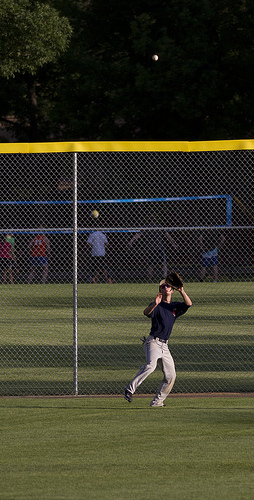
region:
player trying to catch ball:
[132, 35, 203, 353]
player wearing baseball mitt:
[139, 265, 189, 340]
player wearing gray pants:
[138, 275, 186, 414]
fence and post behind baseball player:
[28, 237, 221, 403]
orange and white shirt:
[27, 224, 63, 259]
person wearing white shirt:
[82, 221, 114, 287]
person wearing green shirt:
[7, 223, 22, 259]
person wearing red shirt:
[2, 232, 18, 289]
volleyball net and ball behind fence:
[20, 187, 225, 234]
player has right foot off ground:
[110, 273, 174, 422]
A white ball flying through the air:
[150, 48, 161, 66]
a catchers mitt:
[164, 267, 189, 298]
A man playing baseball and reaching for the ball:
[116, 267, 202, 411]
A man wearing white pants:
[121, 331, 180, 403]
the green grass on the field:
[50, 416, 162, 476]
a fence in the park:
[183, 169, 230, 190]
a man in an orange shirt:
[26, 228, 53, 260]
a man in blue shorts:
[195, 244, 229, 278]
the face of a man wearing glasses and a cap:
[157, 276, 175, 301]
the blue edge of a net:
[19, 191, 236, 213]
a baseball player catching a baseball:
[124, 267, 191, 407]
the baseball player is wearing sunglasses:
[158, 282, 171, 291]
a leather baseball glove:
[164, 270, 185, 288]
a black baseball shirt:
[143, 299, 188, 339]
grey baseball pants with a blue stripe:
[124, 334, 176, 406]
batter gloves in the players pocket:
[139, 334, 148, 344]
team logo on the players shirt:
[171, 310, 175, 317]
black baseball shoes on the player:
[122, 387, 133, 401]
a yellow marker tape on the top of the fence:
[0, 139, 253, 158]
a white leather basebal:
[152, 54, 158, 60]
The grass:
[125, 449, 172, 487]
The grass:
[136, 459, 161, 494]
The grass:
[139, 441, 159, 487]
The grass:
[160, 427, 185, 495]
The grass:
[158, 479, 164, 493]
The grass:
[143, 399, 163, 465]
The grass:
[166, 455, 191, 498]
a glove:
[134, 254, 193, 343]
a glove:
[119, 243, 208, 301]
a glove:
[140, 257, 179, 290]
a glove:
[146, 228, 239, 359]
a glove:
[144, 260, 180, 329]